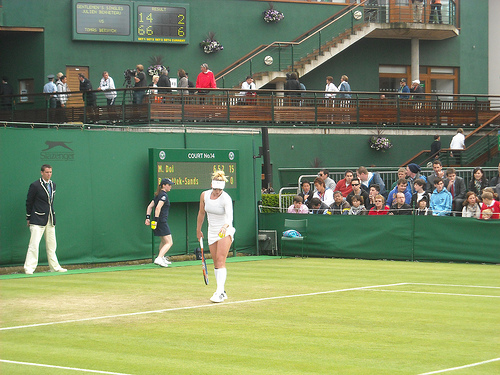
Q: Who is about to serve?
A: The player in white.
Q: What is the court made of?
A: Grass.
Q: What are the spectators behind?
A: The green barrier.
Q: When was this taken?
A: During a match.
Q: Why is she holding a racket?
A: To play tennis.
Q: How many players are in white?
A: One.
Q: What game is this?
A: Singles tennis.